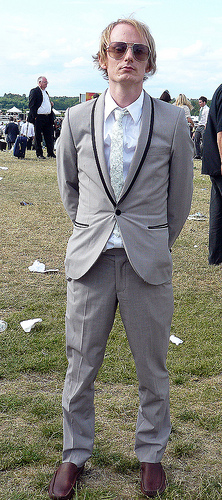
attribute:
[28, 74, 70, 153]
man — old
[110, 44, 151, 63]
glasses — brown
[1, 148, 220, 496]
grass — slightly burned, green, short, thin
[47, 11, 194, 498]
man — mad, tall, standing, white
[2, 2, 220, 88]
sky — partly cloudy, white, big, open, clear, bright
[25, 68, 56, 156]
suit — black